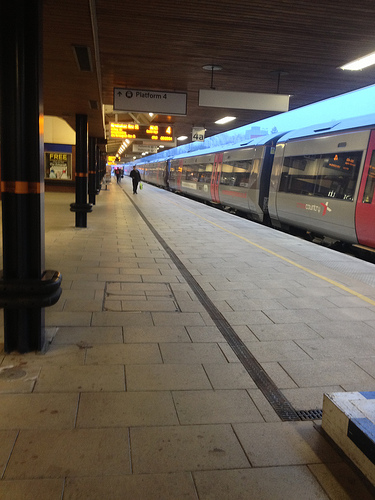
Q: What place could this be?
A: It is a sidewalk.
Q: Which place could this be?
A: It is a sidewalk.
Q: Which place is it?
A: It is a sidewalk.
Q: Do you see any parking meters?
A: No, there are no parking meters.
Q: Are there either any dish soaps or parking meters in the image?
A: No, there are no parking meters or dish soaps.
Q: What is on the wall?
A: The poster is on the wall.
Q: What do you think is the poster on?
A: The poster is on the wall.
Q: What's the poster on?
A: The poster is on the wall.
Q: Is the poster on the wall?
A: Yes, the poster is on the wall.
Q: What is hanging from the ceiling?
A: The sign is hanging from the ceiling.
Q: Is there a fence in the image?
A: No, there are no fences.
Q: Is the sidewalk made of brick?
A: Yes, the sidewalk is made of brick.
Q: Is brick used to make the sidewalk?
A: Yes, the sidewalk is made of brick.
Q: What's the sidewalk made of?
A: The sidewalk is made of brick.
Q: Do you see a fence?
A: No, there are no fences.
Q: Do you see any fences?
A: No, there are no fences.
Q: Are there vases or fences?
A: No, there are no fences or vases.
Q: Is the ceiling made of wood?
A: Yes, the ceiling is made of wood.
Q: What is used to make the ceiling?
A: The ceiling is made of wood.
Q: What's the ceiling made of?
A: The ceiling is made of wood.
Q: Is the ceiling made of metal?
A: No, the ceiling is made of wood.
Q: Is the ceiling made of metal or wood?
A: The ceiling is made of wood.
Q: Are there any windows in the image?
A: Yes, there are windows.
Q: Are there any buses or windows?
A: Yes, there are windows.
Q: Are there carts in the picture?
A: No, there are no carts.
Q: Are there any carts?
A: No, there are no carts.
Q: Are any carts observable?
A: No, there are no carts.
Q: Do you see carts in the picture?
A: No, there are no carts.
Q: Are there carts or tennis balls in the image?
A: No, there are no carts or tennis balls.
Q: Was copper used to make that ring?
A: Yes, the ring is made of copper.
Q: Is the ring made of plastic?
A: No, the ring is made of copper.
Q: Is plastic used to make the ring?
A: No, the ring is made of copper.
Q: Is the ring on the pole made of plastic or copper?
A: The ring is made of copper.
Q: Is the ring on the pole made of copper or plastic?
A: The ring is made of copper.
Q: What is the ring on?
A: The ring is on the pole.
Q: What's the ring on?
A: The ring is on the pole.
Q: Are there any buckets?
A: No, there are no buckets.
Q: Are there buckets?
A: No, there are no buckets.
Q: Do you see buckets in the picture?
A: No, there are no buckets.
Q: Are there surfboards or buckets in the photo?
A: No, there are no buckets or surfboards.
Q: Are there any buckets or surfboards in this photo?
A: No, there are no buckets or surfboards.